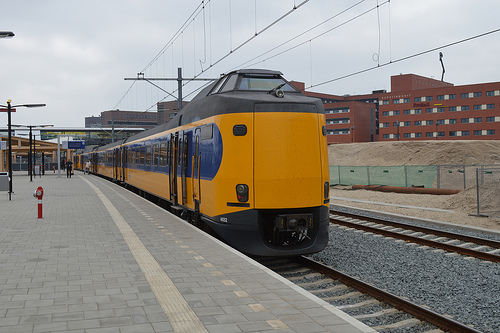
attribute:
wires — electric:
[92, 0, 284, 118]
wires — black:
[184, 6, 371, 64]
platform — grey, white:
[0, 166, 384, 331]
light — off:
[23, 102, 48, 110]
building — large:
[346, 70, 498, 129]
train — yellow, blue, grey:
[148, 90, 343, 265]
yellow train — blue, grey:
[75, 97, 259, 200]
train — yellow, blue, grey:
[89, 78, 327, 243]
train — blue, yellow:
[108, 57, 340, 262]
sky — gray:
[34, 10, 142, 118]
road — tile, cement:
[26, 160, 134, 331]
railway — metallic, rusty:
[443, 229, 488, 257]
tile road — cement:
[0, 170, 372, 330]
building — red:
[288, 70, 499, 148]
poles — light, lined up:
[3, 80, 55, 200]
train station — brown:
[0, 25, 498, 331]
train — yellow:
[149, 71, 348, 280]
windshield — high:
[238, 73, 295, 94]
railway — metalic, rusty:
[319, 194, 479, 331]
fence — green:
[318, 154, 452, 194]